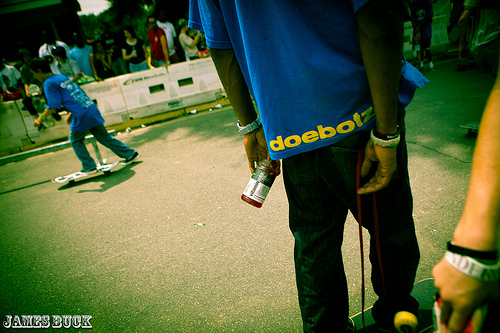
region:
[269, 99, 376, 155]
yellow lettering on blue shirt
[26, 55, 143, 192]
person riding on skateboard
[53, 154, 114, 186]
skateboard being ridden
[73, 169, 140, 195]
shadow of skateboarder on the pavement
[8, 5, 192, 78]
crowd watching the skateboarder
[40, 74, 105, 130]
blue shirt with white lettering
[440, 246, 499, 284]
white wristband with black lettering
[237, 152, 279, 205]
bottle in man's hand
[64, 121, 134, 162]
blue jeans of skateboarder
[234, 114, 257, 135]
white watch band on man's wrist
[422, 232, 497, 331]
man with white an black wrist bands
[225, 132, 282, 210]
man with bottle in left hand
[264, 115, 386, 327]
man with black pants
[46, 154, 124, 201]
white skate board with black squares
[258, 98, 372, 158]
blue shirt with yellow letters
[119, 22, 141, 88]
lady with a bottle in her hand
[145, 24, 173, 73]
man with red shirt watching skaters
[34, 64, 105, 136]
skateboarder with blue shirt with letters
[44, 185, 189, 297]
sun shinning on the ground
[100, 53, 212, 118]
white divider green and blue markings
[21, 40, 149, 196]
boy skateboarding on cement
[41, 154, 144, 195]
boy standing on skateboard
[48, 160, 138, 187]
skateboard is white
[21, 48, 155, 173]
boy wearing blue shirt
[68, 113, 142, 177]
boy wearing blue jeans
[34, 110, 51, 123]
boy with blue armband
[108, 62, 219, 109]
barricade is white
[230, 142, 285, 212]
red drink in clear plastic bottle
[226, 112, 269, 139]
man wearing white watch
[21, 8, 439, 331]
two people wearing blue shirts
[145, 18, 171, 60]
man wearing red shirt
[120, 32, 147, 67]
woman wearing black shirt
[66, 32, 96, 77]
man wearing light blue shirt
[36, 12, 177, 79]
two men wearing white shirts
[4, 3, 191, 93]
spectators watching the skateboarder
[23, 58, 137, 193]
man riding white skateboard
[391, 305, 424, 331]
yellow wheel of skateboard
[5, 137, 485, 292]
patch of sunlight on the pavement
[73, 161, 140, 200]
shadow of skateboard on pavement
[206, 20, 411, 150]
blue and yellow shirt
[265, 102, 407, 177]
yellow letters on shirt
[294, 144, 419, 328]
boy has blue pants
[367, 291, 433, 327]
yellow wheel on skateboard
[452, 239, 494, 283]
person wears two bracelets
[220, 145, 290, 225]
boy holds drink bottle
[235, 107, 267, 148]
boy wears white watch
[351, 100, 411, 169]
black and white bracelets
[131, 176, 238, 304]
grey concrete next to boy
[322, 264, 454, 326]
boy on black skateboard